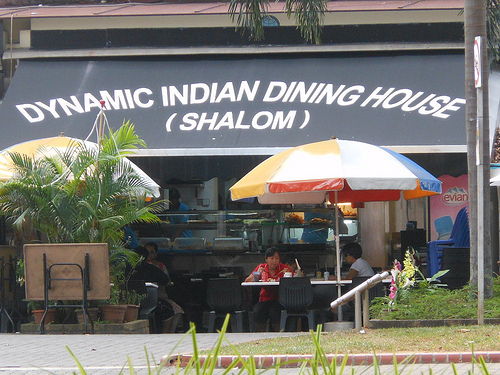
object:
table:
[237, 262, 428, 320]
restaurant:
[0, 0, 482, 304]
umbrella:
[228, 136, 440, 205]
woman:
[244, 245, 296, 332]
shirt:
[250, 263, 293, 303]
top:
[344, 241, 365, 252]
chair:
[205, 277, 250, 333]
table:
[21, 240, 112, 336]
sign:
[0, 55, 467, 149]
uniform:
[163, 202, 192, 233]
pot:
[100, 304, 127, 323]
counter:
[241, 281, 357, 284]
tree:
[0, 116, 175, 305]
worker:
[159, 187, 195, 237]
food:
[281, 212, 309, 225]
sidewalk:
[0, 331, 499, 374]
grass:
[198, 323, 500, 354]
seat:
[426, 203, 470, 281]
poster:
[429, 173, 470, 244]